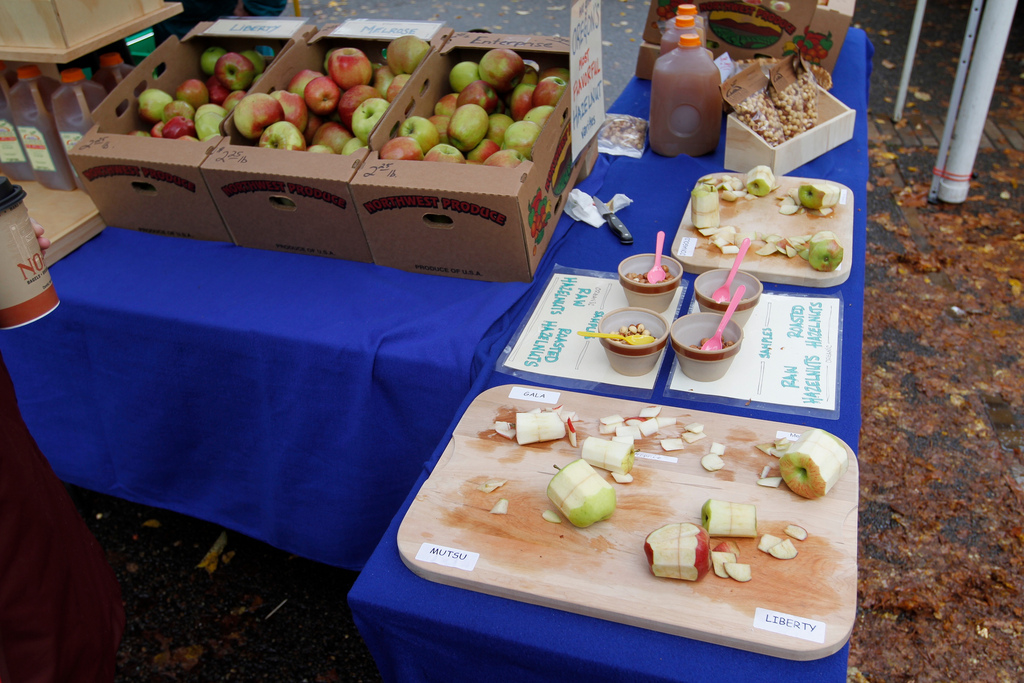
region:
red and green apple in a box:
[296, 68, 335, 111]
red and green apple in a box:
[349, 93, 391, 126]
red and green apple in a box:
[446, 100, 482, 152]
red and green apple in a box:
[155, 90, 191, 128]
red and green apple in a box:
[207, 40, 258, 89]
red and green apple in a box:
[378, 135, 420, 161]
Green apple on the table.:
[542, 449, 623, 533]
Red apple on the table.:
[637, 516, 726, 592]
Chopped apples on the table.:
[589, 402, 688, 438]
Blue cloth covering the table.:
[187, 276, 488, 458]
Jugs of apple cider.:
[636, 13, 725, 151]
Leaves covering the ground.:
[890, 208, 995, 522]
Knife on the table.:
[580, 180, 644, 258]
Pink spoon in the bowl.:
[706, 227, 755, 310]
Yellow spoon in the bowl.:
[566, 325, 656, 355]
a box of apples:
[343, 23, 584, 284]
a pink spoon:
[644, 223, 676, 287]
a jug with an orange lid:
[643, 26, 735, 163]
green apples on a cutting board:
[666, 161, 859, 291]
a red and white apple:
[643, 516, 716, 592]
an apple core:
[507, 405, 580, 448]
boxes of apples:
[65, 10, 591, 277]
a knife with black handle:
[587, 191, 644, 249]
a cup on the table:
[0, 174, 65, 339]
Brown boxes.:
[78, 4, 603, 290]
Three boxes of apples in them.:
[88, 16, 583, 277]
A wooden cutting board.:
[393, 379, 872, 658]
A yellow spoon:
[571, 312, 664, 363]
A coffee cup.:
[4, 176, 62, 355]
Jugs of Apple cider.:
[650, 9, 727, 165]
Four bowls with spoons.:
[595, 250, 770, 384]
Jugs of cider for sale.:
[633, 4, 719, 163]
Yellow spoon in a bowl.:
[567, 315, 656, 366]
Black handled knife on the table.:
[574, 190, 639, 247]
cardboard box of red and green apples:
[346, 25, 607, 294]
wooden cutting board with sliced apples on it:
[387, 372, 869, 671]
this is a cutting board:
[378, 342, 928, 669]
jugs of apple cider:
[647, 9, 737, 166]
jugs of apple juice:
[616, 3, 744, 172]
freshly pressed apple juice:
[620, 2, 758, 192]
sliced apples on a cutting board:
[594, 392, 706, 482]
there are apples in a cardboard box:
[95, 13, 621, 289]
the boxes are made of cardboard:
[63, 15, 645, 316]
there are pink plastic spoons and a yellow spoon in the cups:
[550, 222, 844, 415]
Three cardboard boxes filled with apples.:
[70, 12, 595, 281]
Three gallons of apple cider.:
[648, 6, 724, 168]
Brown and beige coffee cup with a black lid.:
[1, 177, 59, 332]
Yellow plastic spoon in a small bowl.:
[577, 316, 651, 351]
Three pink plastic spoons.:
[645, 227, 763, 360]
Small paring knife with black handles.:
[589, 189, 634, 243]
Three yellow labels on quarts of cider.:
[0, 120, 81, 190]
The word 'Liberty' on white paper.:
[751, 603, 827, 643]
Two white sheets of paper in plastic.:
[491, 260, 852, 425]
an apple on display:
[643, 537, 710, 592]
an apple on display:
[500, 83, 555, 147]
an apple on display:
[424, 86, 473, 129]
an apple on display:
[435, 83, 513, 156]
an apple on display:
[471, 60, 517, 86]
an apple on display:
[359, 83, 391, 147]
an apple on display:
[327, 48, 373, 118]